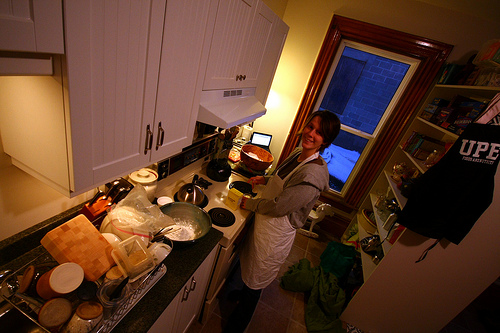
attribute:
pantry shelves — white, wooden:
[327, 62, 498, 328]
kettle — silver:
[174, 179, 204, 204]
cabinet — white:
[255, 15, 290, 105]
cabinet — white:
[68, 9, 209, 194]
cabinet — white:
[206, 0, 271, 93]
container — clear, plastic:
[50, 243, 107, 315]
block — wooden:
[80, 195, 115, 222]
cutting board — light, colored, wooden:
[24, 205, 164, 282]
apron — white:
[237, 144, 321, 289]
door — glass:
[316, 37, 419, 205]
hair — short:
[318, 110, 336, 135]